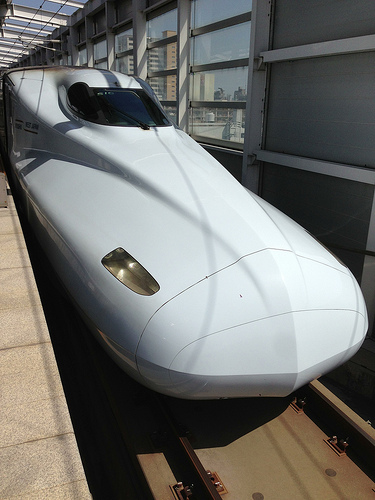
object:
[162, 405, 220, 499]
metal rail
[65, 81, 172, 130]
window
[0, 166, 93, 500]
side walk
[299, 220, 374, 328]
spot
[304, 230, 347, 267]
headlight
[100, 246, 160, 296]
headlight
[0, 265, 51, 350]
tiles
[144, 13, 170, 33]
window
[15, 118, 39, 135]
name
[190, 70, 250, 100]
window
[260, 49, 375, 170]
paneling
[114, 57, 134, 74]
window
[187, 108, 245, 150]
window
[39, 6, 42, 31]
suspension line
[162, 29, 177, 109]
building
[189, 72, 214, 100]
building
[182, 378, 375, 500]
grooves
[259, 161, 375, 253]
paneling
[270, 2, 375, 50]
paneling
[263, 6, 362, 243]
wall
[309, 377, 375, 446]
rail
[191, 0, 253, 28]
window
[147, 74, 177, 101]
window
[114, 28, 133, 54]
window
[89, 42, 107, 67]
window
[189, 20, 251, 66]
windows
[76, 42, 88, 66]
windows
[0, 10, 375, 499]
station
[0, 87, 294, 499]
shadow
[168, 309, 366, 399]
line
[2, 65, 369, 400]
batmobile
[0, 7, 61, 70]
wires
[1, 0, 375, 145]
row